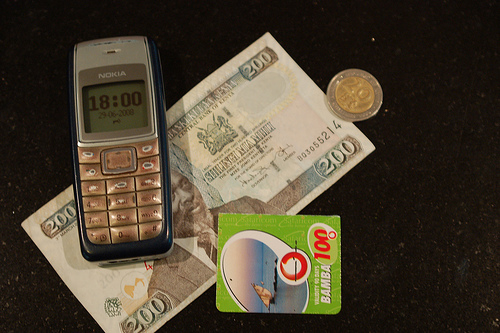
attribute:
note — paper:
[15, 25, 380, 331]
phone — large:
[74, 32, 174, 267]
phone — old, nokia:
[67, 56, 174, 230]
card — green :
[212, 213, 342, 318]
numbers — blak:
[316, 136, 363, 178]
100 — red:
[309, 226, 334, 269]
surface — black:
[398, 161, 497, 319]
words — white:
[316, 260, 336, 306]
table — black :
[7, 10, 496, 325]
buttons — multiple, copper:
[76, 141, 165, 245]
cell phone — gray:
[66, 30, 173, 264]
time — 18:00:
[78, 86, 145, 109]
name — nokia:
[92, 68, 129, 81]